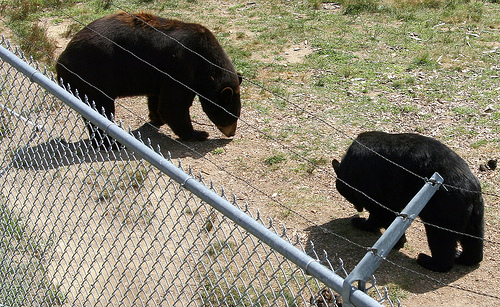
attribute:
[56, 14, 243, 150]
bear — black, adult, walking, big, sniffing, brown, looking down, standing, moving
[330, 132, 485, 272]
bear — black, young, walking, small, standing, sniffing, brown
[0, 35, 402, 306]
fence — chain link, barbed wire, metal, grey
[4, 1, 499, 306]
ground — flat, rocky, dusty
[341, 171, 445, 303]
bracket — support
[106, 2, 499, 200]
wire — barb, barbed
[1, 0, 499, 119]
foliage — green, patch, patchy, low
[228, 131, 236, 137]
nose — light brown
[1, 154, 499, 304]
dirt — brown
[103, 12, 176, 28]
patch — brown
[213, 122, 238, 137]
snout — brown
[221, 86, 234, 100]
ear — tiny, round, perked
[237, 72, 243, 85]
ear — tiny, round, perked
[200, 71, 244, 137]
head — bowed